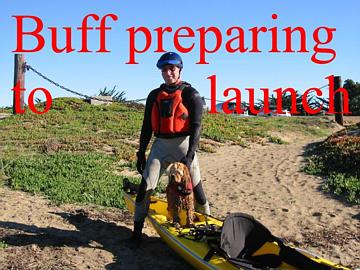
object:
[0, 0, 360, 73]
sky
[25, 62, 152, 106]
rope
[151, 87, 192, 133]
life vest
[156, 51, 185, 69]
helmet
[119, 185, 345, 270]
kayak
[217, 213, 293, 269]
kayak seat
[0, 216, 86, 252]
shadow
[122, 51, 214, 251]
person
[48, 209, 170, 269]
shadow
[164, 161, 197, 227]
dog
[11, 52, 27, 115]
post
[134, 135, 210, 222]
pants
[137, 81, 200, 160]
top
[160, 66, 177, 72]
sunglasses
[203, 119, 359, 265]
road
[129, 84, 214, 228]
wet suit